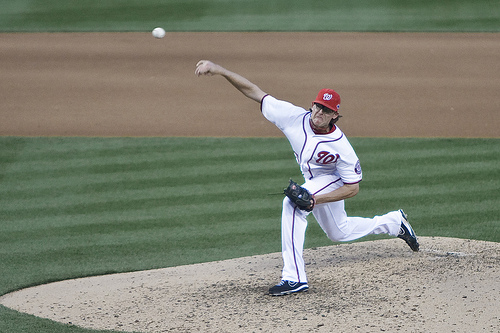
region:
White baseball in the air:
[137, 19, 183, 46]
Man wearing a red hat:
[305, 73, 346, 140]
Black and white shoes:
[260, 274, 327, 298]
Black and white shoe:
[389, 205, 421, 260]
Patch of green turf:
[36, 131, 162, 219]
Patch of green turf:
[32, 217, 179, 262]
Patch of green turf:
[200, 143, 260, 248]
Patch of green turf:
[386, 143, 484, 213]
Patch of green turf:
[416, 210, 498, 234]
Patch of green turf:
[212, 4, 443, 34]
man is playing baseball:
[110, 7, 443, 313]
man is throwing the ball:
[123, 19, 425, 303]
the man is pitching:
[110, 0, 421, 307]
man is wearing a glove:
[260, 169, 360, 239]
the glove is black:
[267, 174, 347, 224]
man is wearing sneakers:
[223, 182, 432, 297]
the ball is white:
[119, 15, 179, 77]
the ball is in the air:
[135, 20, 210, 87]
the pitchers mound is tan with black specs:
[165, 210, 484, 325]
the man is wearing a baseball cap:
[295, 73, 373, 138]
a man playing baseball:
[112, 7, 492, 301]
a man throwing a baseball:
[89, 21, 405, 331]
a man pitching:
[44, 2, 454, 328]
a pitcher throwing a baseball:
[109, 22, 499, 305]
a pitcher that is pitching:
[117, 18, 450, 330]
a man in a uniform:
[196, 34, 467, 326]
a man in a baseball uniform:
[133, 20, 453, 327]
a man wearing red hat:
[229, 13, 461, 293]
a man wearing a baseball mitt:
[194, 14, 448, 325]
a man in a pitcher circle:
[60, 29, 444, 331]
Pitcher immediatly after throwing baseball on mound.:
[193, 60, 418, 295]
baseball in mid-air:
[142, 20, 169, 49]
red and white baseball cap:
[312, 85, 342, 115]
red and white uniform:
[250, 83, 413, 293]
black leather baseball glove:
[277, 169, 317, 223]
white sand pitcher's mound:
[3, 223, 498, 330]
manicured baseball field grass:
[2, 126, 497, 331]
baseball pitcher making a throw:
[190, 53, 436, 298]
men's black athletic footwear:
[264, 275, 312, 304]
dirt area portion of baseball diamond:
[2, 25, 499, 165]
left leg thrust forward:
[258, 170, 355, 303]